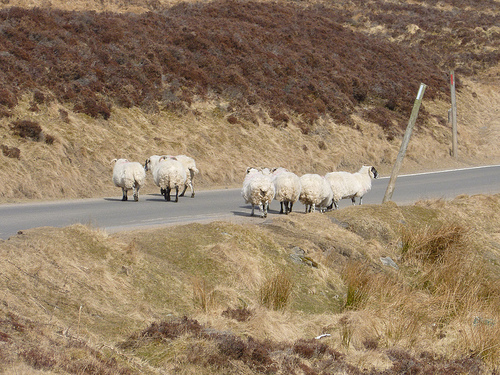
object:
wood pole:
[382, 81, 426, 207]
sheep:
[108, 157, 147, 201]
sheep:
[323, 166, 379, 210]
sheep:
[241, 164, 273, 217]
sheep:
[273, 168, 303, 210]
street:
[0, 164, 499, 239]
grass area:
[1, 192, 497, 373]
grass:
[89, 123, 141, 152]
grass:
[426, 262, 496, 339]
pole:
[379, 82, 428, 205]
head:
[362, 164, 379, 180]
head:
[245, 166, 256, 174]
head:
[271, 165, 286, 173]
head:
[143, 155, 158, 171]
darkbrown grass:
[0, 0, 499, 142]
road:
[0, 162, 499, 240]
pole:
[450, 69, 458, 157]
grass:
[2, 158, 38, 190]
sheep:
[152, 155, 188, 203]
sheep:
[298, 173, 334, 213]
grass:
[111, 281, 149, 321]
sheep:
[143, 154, 199, 198]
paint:
[451, 74, 453, 85]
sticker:
[450, 74, 454, 85]